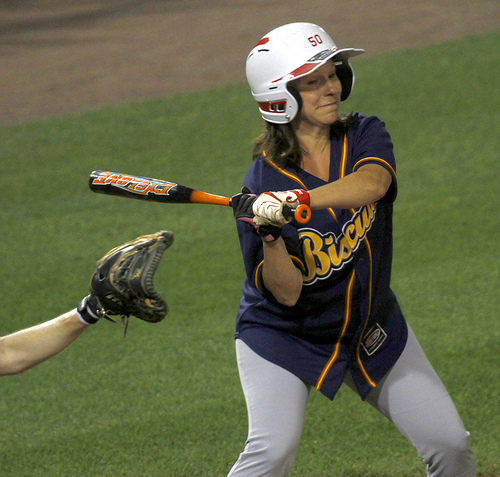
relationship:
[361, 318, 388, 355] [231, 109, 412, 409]
label on jersey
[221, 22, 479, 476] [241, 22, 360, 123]
player wearing helmet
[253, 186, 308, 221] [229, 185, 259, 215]
glove doesnt match glove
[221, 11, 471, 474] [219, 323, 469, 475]
player wearing pants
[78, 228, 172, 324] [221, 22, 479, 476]
hand beside player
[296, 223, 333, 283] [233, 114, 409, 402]
b on jersey